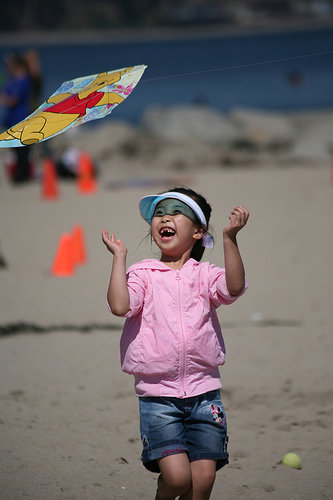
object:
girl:
[102, 184, 249, 500]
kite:
[0, 61, 148, 146]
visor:
[138, 190, 208, 230]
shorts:
[137, 394, 229, 473]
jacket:
[119, 257, 248, 398]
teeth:
[159, 229, 174, 239]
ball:
[282, 452, 302, 470]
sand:
[261, 176, 331, 318]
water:
[149, 35, 292, 102]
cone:
[39, 156, 58, 201]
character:
[211, 402, 227, 428]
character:
[63, 74, 130, 118]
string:
[148, 39, 330, 91]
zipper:
[174, 269, 186, 398]